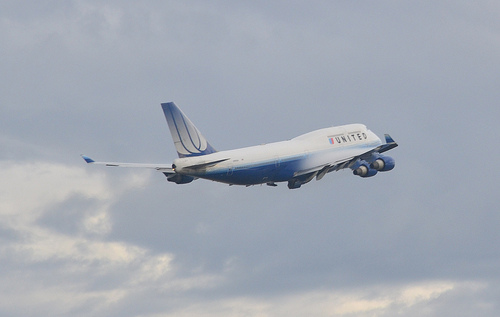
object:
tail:
[78, 153, 174, 176]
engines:
[349, 159, 378, 177]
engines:
[368, 156, 395, 173]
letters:
[326, 132, 367, 144]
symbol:
[328, 138, 335, 144]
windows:
[325, 132, 369, 145]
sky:
[0, 0, 500, 317]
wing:
[336, 143, 395, 170]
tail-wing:
[183, 157, 232, 172]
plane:
[79, 100, 397, 189]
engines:
[162, 171, 193, 186]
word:
[327, 132, 369, 144]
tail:
[159, 99, 219, 167]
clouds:
[0, 0, 500, 317]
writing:
[325, 132, 367, 144]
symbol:
[328, 138, 334, 144]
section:
[0, 215, 500, 317]